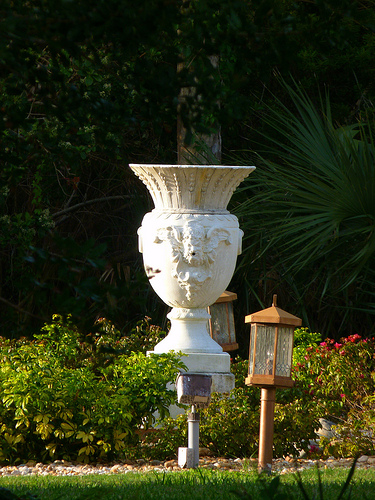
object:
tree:
[1, 0, 371, 325]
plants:
[295, 329, 374, 461]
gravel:
[1, 449, 193, 481]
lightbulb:
[212, 315, 221, 331]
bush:
[296, 333, 374, 461]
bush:
[0, 312, 174, 461]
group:
[0, 309, 183, 460]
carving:
[152, 218, 232, 306]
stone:
[128, 161, 254, 369]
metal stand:
[186, 404, 201, 466]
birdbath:
[132, 162, 257, 373]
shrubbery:
[0, 312, 373, 464]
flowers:
[291, 332, 375, 456]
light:
[172, 370, 212, 469]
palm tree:
[179, 90, 374, 317]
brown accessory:
[241, 292, 306, 477]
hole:
[191, 252, 196, 256]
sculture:
[128, 161, 258, 374]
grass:
[0, 463, 375, 500]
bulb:
[266, 340, 285, 371]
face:
[154, 224, 233, 305]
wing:
[153, 225, 184, 262]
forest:
[0, 2, 370, 342]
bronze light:
[206, 290, 238, 349]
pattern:
[153, 218, 233, 306]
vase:
[124, 161, 257, 362]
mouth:
[128, 163, 258, 211]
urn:
[126, 163, 259, 373]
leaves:
[287, 331, 372, 446]